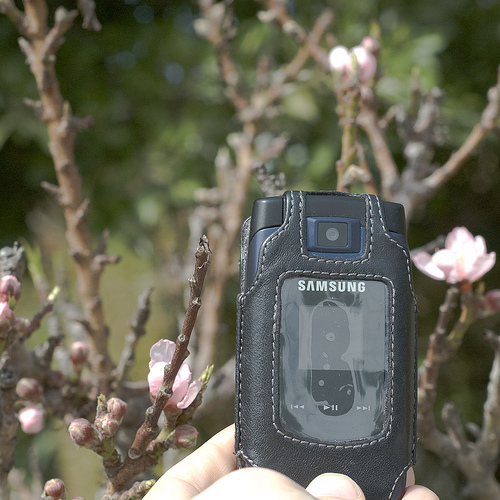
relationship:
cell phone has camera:
[234, 190, 417, 499] [315, 222, 348, 253]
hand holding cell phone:
[128, 417, 438, 498] [234, 190, 417, 499]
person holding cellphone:
[152, 439, 414, 496] [249, 194, 419, 460]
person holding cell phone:
[140, 423, 441, 500] [240, 185, 422, 497]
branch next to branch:
[357, 52, 497, 227] [68, 235, 218, 499]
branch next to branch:
[3, 2, 115, 364] [68, 235, 218, 499]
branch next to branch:
[184, 2, 336, 397] [68, 235, 218, 499]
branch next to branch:
[111, 283, 155, 388] [68, 235, 218, 499]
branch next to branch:
[3, 285, 58, 348] [68, 235, 218, 499]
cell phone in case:
[234, 190, 417, 499] [229, 183, 423, 498]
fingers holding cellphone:
[162, 414, 257, 498] [198, 183, 449, 440]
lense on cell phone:
[314, 219, 354, 254] [234, 190, 417, 499]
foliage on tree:
[68, 26, 199, 220] [33, 0, 210, 357]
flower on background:
[147, 338, 202, 409] [3, 4, 494, 489]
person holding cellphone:
[140, 423, 441, 500] [236, 190, 418, 498]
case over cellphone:
[229, 183, 423, 498] [245, 194, 407, 497]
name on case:
[295, 275, 370, 294] [271, 191, 398, 347]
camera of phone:
[304, 211, 364, 255] [222, 181, 425, 498]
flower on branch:
[147, 335, 202, 405] [159, 402, 195, 450]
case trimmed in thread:
[229, 183, 423, 498] [249, 248, 421, 474]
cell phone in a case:
[245, 193, 408, 498] [229, 183, 423, 498]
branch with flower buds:
[8, 285, 61, 351] [66, 338, 89, 365]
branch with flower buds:
[8, 285, 61, 351] [18, 402, 48, 434]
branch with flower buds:
[8, 285, 61, 351] [1, 272, 21, 304]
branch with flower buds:
[8, 285, 61, 351] [0, 299, 13, 334]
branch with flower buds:
[8, 285, 61, 351] [15, 375, 45, 403]